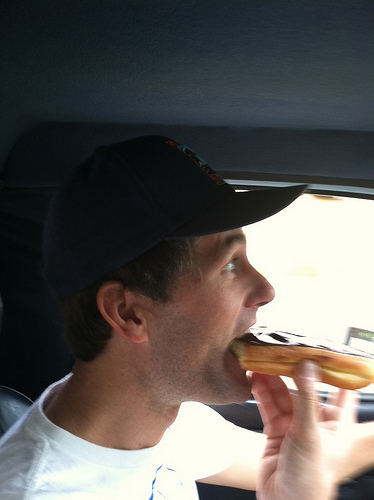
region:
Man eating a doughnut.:
[48, 151, 360, 396]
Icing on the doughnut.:
[204, 303, 354, 392]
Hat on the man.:
[44, 134, 309, 307]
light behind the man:
[219, 248, 341, 331]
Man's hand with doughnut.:
[200, 316, 351, 449]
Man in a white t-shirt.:
[10, 352, 194, 498]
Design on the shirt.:
[126, 450, 195, 494]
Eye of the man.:
[151, 185, 333, 323]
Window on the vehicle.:
[180, 136, 371, 382]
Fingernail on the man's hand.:
[288, 347, 344, 400]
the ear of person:
[95, 278, 153, 347]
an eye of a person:
[221, 251, 242, 279]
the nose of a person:
[244, 258, 277, 311]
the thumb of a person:
[293, 356, 323, 425]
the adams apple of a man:
[161, 403, 181, 433]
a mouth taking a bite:
[228, 314, 271, 381]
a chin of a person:
[225, 379, 256, 408]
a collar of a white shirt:
[32, 397, 119, 453]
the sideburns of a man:
[140, 271, 182, 309]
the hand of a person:
[249, 368, 354, 495]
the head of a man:
[41, 134, 288, 410]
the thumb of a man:
[278, 359, 322, 476]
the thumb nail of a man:
[297, 358, 317, 379]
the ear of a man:
[92, 277, 159, 350]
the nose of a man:
[240, 252, 280, 311]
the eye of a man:
[213, 250, 245, 279]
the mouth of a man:
[221, 317, 264, 367]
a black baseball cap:
[30, 127, 314, 307]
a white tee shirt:
[0, 365, 268, 498]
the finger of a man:
[242, 363, 282, 422]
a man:
[95, 228, 227, 496]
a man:
[99, 390, 156, 487]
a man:
[95, 265, 168, 407]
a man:
[137, 312, 215, 497]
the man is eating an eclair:
[215, 318, 372, 395]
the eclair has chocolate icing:
[230, 321, 373, 369]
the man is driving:
[1, 130, 369, 497]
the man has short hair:
[46, 234, 207, 370]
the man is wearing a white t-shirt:
[0, 365, 271, 498]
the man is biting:
[223, 314, 265, 380]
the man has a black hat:
[37, 129, 313, 306]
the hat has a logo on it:
[168, 136, 229, 197]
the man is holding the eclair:
[220, 324, 372, 401]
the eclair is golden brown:
[227, 338, 372, 397]